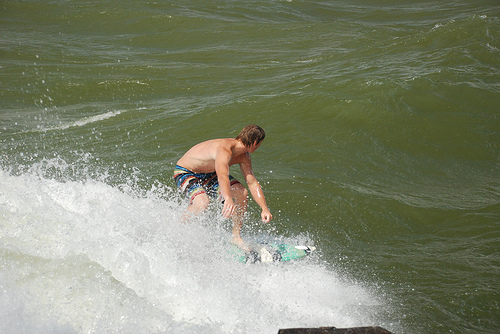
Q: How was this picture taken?
A: Camera.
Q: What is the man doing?
A: Water skiing.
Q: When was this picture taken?
A: Daytime.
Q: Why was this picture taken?
A: To show the beauty of water skiing.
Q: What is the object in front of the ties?
A: Boat.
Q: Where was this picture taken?
A: Water.